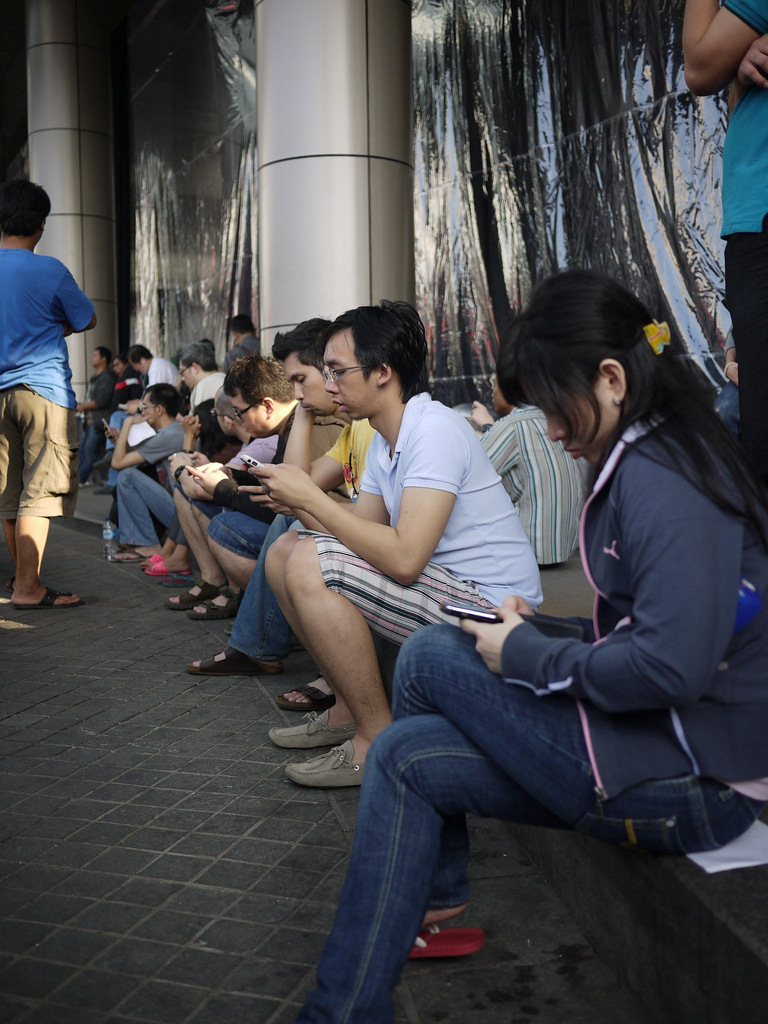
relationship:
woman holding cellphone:
[312, 266, 762, 1021] [440, 602, 500, 624]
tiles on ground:
[7, 420, 766, 1013] [5, 474, 766, 974]